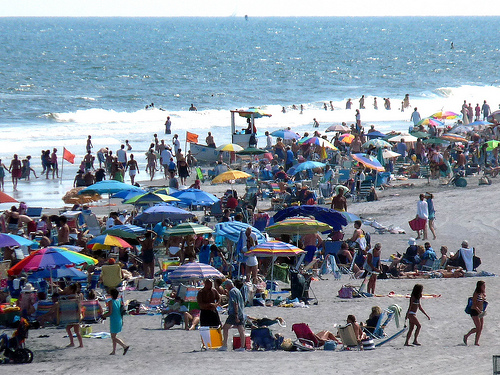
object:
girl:
[25, 155, 39, 180]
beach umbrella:
[244, 237, 308, 303]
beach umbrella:
[8, 245, 100, 296]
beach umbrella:
[211, 168, 252, 198]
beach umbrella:
[350, 153, 386, 172]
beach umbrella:
[263, 213, 334, 264]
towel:
[379, 288, 441, 298]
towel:
[64, 328, 112, 340]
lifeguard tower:
[230, 107, 272, 149]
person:
[61, 283, 85, 346]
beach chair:
[35, 299, 83, 326]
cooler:
[232, 334, 251, 351]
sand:
[3, 173, 499, 371]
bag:
[361, 337, 376, 350]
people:
[188, 103, 197, 111]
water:
[2, 16, 497, 92]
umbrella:
[213, 219, 263, 247]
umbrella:
[437, 131, 468, 144]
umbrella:
[420, 109, 462, 121]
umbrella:
[167, 261, 225, 282]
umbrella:
[350, 147, 386, 175]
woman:
[100, 286, 131, 356]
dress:
[108, 298, 123, 333]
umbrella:
[212, 168, 251, 199]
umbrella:
[264, 210, 334, 256]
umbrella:
[136, 201, 195, 223]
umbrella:
[162, 222, 216, 237]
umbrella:
[212, 139, 248, 159]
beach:
[2, 146, 498, 371]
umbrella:
[77, 229, 137, 254]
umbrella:
[6, 242, 100, 305]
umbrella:
[244, 238, 308, 303]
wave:
[55, 94, 484, 134]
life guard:
[242, 118, 257, 135]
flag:
[61, 146, 76, 178]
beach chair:
[362, 304, 408, 348]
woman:
[402, 280, 434, 352]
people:
[348, 220, 367, 254]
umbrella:
[77, 179, 141, 195]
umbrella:
[85, 232, 133, 251]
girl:
[463, 280, 487, 346]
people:
[214, 152, 231, 169]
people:
[18, 283, 39, 316]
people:
[489, 143, 499, 179]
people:
[397, 138, 410, 157]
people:
[253, 160, 273, 185]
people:
[85, 134, 93, 154]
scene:
[79, 58, 442, 345]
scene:
[73, 96, 445, 354]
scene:
[175, 85, 416, 243]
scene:
[306, 58, 487, 239]